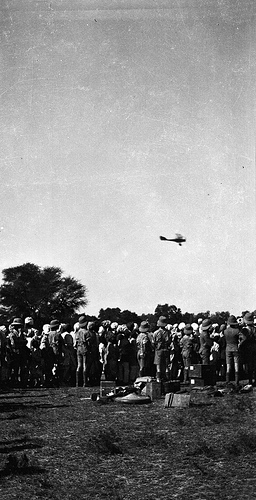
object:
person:
[75, 314, 91, 389]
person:
[180, 322, 196, 382]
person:
[47, 319, 64, 382]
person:
[199, 318, 214, 364]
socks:
[76, 371, 79, 383]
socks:
[83, 371, 86, 382]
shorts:
[153, 351, 169, 366]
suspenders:
[0, 313, 256, 387]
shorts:
[77, 352, 87, 363]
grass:
[0, 385, 256, 500]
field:
[0, 381, 255, 499]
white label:
[190, 379, 195, 385]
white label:
[189, 365, 194, 370]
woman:
[39, 324, 51, 351]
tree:
[3, 258, 88, 326]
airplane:
[159, 232, 187, 247]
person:
[224, 314, 240, 384]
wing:
[174, 233, 183, 238]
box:
[188, 362, 214, 377]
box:
[189, 378, 216, 389]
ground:
[0, 378, 254, 498]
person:
[135, 320, 150, 379]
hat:
[178, 322, 185, 329]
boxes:
[99, 380, 116, 399]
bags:
[157, 329, 170, 359]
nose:
[183, 238, 187, 241]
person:
[152, 315, 173, 382]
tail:
[159, 236, 167, 240]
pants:
[225, 350, 238, 363]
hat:
[139, 320, 150, 332]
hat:
[183, 323, 193, 335]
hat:
[228, 315, 239, 326]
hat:
[157, 315, 168, 328]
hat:
[201, 318, 211, 331]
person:
[238, 312, 255, 387]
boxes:
[146, 381, 161, 400]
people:
[10, 317, 24, 387]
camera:
[237, 323, 247, 330]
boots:
[235, 371, 240, 384]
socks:
[225, 371, 229, 382]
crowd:
[0, 309, 256, 392]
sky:
[0, 0, 255, 317]